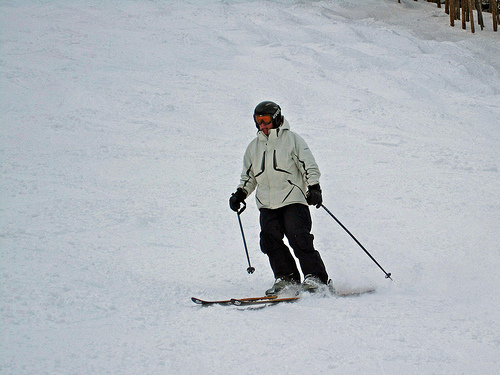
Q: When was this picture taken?
A: Daylight.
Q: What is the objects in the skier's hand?
A: Ski poles.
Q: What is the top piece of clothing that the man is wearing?
A: Jacket.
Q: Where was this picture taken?
A: On a mountain.